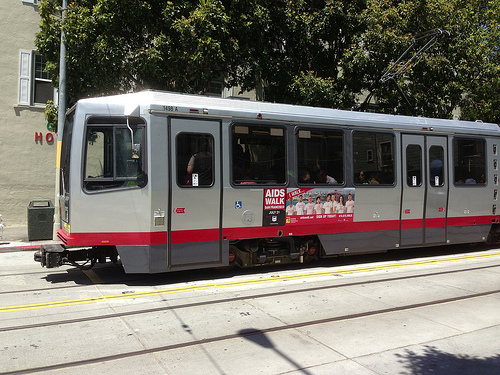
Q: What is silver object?
A: Train.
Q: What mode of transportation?
A: Train.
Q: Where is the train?
A: On tracks.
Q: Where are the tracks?
A: On sidewalk.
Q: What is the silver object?
A: Train.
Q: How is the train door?
A: Closed.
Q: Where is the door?
A: On train.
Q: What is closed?
A: Door.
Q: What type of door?
A: Train.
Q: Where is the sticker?
A: Door window.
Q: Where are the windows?
A: On train.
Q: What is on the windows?
A: Stickers.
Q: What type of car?
A: Transit.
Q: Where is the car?
A: On train.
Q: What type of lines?
A: Power.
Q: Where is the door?
A: On trolley.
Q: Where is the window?
A: On trolley.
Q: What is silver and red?
A: Trolley.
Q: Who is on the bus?
A: Passengers.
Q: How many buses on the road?
A: One.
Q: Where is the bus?
A: The street.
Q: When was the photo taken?
A: Day time.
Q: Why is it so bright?
A: Sunny.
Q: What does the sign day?
A: Aids walk.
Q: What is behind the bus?
A: A tree.